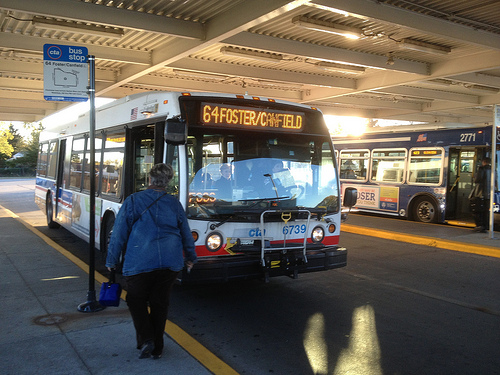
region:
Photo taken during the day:
[10, 9, 495, 363]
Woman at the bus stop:
[90, 163, 212, 364]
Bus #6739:
[267, 215, 319, 244]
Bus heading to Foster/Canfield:
[196, 98, 313, 134]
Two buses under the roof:
[26, 103, 498, 273]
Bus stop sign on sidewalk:
[37, 39, 109, 316]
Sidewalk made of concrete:
[6, 225, 191, 367]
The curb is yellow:
[0, 190, 225, 370]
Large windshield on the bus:
[187, 114, 326, 215]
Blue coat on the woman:
[101, 190, 199, 282]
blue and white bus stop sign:
[43, 43, 88, 98]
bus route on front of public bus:
[201, 102, 306, 132]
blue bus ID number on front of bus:
[281, 221, 306, 236]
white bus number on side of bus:
[458, 128, 475, 143]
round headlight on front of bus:
[203, 229, 224, 253]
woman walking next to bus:
[100, 163, 198, 365]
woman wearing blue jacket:
[94, 162, 199, 362]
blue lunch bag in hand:
[94, 265, 121, 307]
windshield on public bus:
[181, 123, 341, 223]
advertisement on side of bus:
[340, 181, 397, 213]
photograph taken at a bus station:
[11, 13, 488, 360]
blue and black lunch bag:
[90, 260, 134, 313]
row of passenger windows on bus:
[31, 126, 126, 187]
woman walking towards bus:
[87, 163, 202, 360]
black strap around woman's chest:
[123, 190, 174, 233]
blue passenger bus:
[345, 121, 499, 213]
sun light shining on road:
[294, 298, 387, 370]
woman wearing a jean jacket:
[101, 165, 206, 285]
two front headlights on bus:
[201, 212, 328, 255]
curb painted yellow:
[362, 213, 498, 263]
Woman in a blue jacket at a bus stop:
[40, 42, 193, 360]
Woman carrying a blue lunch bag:
[100, 163, 201, 361]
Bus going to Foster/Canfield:
[33, 93, 350, 270]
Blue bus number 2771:
[336, 124, 498, 236]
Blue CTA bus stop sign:
[37, 40, 101, 316]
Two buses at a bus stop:
[37, 99, 498, 273]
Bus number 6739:
[180, 85, 347, 280]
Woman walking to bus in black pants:
[95, 155, 197, 367]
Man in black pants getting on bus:
[468, 148, 498, 237]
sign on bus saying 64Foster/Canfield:
[182, 93, 330, 135]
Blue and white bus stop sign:
[42, 42, 89, 100]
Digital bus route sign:
[197, 102, 309, 132]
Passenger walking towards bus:
[96, 162, 196, 357]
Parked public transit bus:
[32, 89, 350, 284]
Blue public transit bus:
[337, 120, 499, 228]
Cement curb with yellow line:
[0, 203, 233, 373]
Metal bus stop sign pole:
[79, 54, 106, 317]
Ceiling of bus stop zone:
[1, 2, 497, 122]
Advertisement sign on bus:
[341, 183, 401, 215]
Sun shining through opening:
[326, 114, 371, 136]